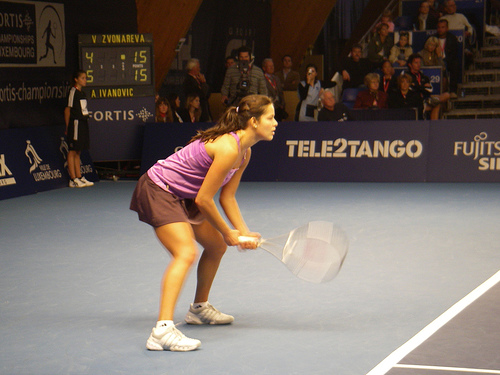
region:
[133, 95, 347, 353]
woman holding tennis racket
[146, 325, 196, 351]
woman wearing pair of white sneakers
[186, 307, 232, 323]
woman wearing pair of white sneakers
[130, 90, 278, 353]
woman is wearing pony tail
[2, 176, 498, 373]
tennis court floor is blue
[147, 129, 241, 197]
purple shirt has spaghetti straps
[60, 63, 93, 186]
man wearing black shorts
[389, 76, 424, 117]
person wearing black shirt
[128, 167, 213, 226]
tennis skirt is short and purple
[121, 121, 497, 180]
sign is navy with white writing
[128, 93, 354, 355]
woman playing tennis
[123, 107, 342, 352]
person playing tennis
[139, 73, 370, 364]
woman holding tennis racket with both hands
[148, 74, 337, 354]
person holding tennis racket with both hands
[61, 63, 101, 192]
person wearing black outfit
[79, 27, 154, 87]
electronic tennis score board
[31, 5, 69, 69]
drawing of person holding tennis racket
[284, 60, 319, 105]
person taking a picture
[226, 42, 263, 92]
cameraman with a camera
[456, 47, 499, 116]
bleacher stair way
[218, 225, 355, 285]
The blurry tennis racket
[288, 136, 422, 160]
The words tele 2 tango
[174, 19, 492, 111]
The crowd of people watching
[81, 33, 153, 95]
The score board behind the man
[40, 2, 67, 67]
The advertisement of the tennis player on left side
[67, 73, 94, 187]
The man standing off to the side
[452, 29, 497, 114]
The stairs located in the stands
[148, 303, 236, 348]
The tennis players shoes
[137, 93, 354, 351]
The tennis player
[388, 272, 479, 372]
The lines on the tennis court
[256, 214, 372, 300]
silver tennis racket in motion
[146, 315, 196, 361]
right white shoe of girl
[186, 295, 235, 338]
left white shoe of girl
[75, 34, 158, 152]
digital scoreboard on left side of photo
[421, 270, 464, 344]
white line painted on ground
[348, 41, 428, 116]
spectators watching the game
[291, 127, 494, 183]
board with names of sponsors on it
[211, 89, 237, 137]
ponytail on back of girl's head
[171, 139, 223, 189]
purple tank top on girl in photo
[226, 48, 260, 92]
camera filming the tennis match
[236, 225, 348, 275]
a blurry tennis racket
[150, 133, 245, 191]
a pink shirt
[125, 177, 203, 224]
a pair of brown pants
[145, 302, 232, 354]
a pair of white athletic sneakers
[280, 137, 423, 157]
a written advertisement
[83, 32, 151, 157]
a digital scoreboard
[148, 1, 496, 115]
a crowd of viewers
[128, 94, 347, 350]
a woman intently playing tennis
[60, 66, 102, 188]
a ballboy patiently waiting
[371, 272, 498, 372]
the corner of a tennis court